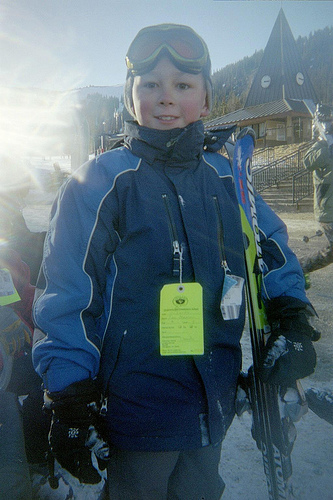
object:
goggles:
[125, 24, 207, 73]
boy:
[28, 21, 321, 500]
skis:
[232, 127, 288, 499]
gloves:
[48, 374, 112, 488]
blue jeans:
[104, 446, 224, 499]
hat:
[123, 24, 215, 115]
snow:
[218, 327, 332, 500]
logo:
[68, 426, 80, 438]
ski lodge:
[202, 7, 333, 150]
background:
[0, 3, 333, 498]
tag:
[159, 281, 204, 357]